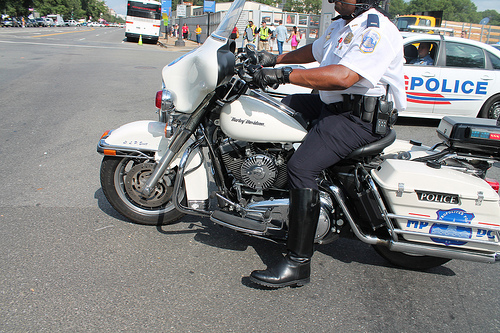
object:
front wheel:
[100, 151, 187, 226]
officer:
[237, 0, 407, 290]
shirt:
[310, 7, 405, 112]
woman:
[287, 26, 301, 51]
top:
[291, 31, 299, 47]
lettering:
[414, 190, 459, 204]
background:
[415, 190, 459, 204]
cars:
[0, 15, 23, 28]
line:
[31, 29, 94, 38]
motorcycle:
[97, 0, 500, 271]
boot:
[237, 183, 322, 288]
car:
[265, 25, 500, 120]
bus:
[124, 0, 161, 45]